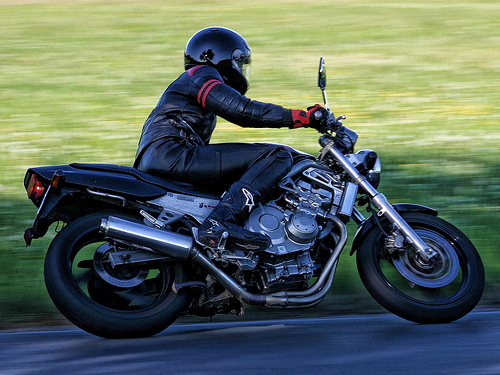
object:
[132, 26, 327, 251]
person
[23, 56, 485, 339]
motorcycle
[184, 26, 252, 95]
helmet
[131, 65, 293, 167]
jacket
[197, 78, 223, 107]
stripes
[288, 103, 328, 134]
glove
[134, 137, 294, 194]
pants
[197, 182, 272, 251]
boot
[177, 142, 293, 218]
leg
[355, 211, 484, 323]
front wheel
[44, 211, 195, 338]
rear wheel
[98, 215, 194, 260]
muffler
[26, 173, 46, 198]
tail light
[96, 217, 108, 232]
tail pipe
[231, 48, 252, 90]
visor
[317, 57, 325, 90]
rearview mirror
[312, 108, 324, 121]
handlebar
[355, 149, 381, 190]
headlight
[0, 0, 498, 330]
field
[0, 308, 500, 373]
road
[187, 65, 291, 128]
sleeve